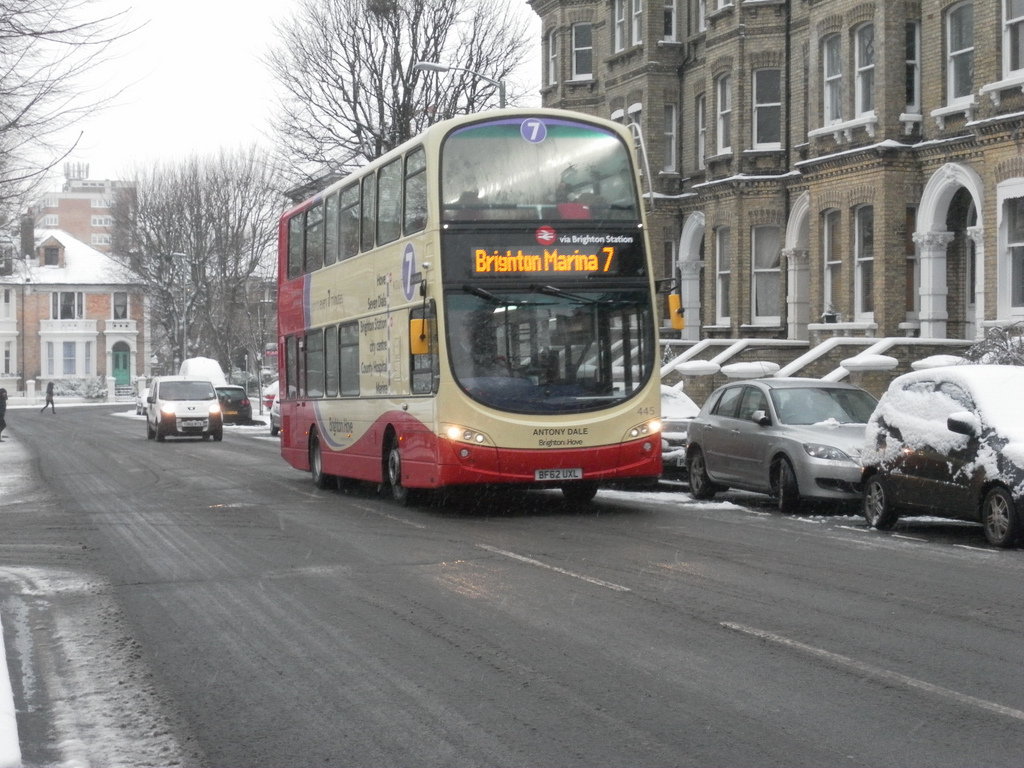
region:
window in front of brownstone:
[547, 35, 561, 84]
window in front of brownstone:
[573, 21, 596, 81]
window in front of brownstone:
[821, 207, 846, 318]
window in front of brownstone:
[852, 204, 873, 322]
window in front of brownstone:
[695, 95, 707, 169]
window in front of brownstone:
[713, 64, 736, 155]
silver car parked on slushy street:
[687, 371, 894, 512]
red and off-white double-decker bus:
[270, 101, 672, 509]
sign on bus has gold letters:
[445, 231, 643, 276]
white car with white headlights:
[144, 368, 227, 438]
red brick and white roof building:
[1, 216, 153, 407]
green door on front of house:
[110, 342, 134, 391]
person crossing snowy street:
[39, 379, 63, 418]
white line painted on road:
[470, 535, 638, 605]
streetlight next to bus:
[412, 57, 512, 118]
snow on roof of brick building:
[26, 226, 153, 392]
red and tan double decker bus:
[269, 102, 668, 507]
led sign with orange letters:
[450, 232, 650, 476]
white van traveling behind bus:
[138, 99, 666, 493]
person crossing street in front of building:
[20, 372, 100, 418]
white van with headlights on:
[140, 375, 227, 445]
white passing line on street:
[450, 523, 685, 631]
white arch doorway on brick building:
[906, 150, 989, 346]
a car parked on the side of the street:
[674, 371, 883, 518]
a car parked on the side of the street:
[212, 377, 252, 426]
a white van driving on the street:
[143, 370, 227, 443]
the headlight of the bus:
[444, 423, 460, 443]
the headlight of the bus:
[643, 415, 663, 432]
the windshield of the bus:
[443, 282, 652, 401]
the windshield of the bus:
[438, 115, 638, 218]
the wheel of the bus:
[301, 423, 334, 475]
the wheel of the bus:
[377, 426, 415, 499]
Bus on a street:
[263, 99, 681, 526]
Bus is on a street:
[263, 96, 696, 526]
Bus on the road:
[269, 102, 693, 526]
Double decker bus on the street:
[258, 102, 682, 539]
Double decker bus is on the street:
[263, 102, 693, 532]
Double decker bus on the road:
[266, 98, 668, 523]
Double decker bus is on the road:
[260, 98, 673, 531]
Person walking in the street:
[35, 368, 70, 420]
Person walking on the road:
[27, 370, 70, 419]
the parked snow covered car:
[681, 376, 879, 519]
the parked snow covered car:
[860, 363, 1022, 534]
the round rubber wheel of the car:
[680, 445, 712, 496]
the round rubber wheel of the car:
[773, 453, 796, 512]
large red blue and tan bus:
[277, 105, 660, 511]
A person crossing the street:
[1, 380, 1022, 766]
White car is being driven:
[146, 375, 222, 440]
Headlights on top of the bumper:
[437, 422, 660, 489]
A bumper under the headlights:
[438, 419, 664, 486]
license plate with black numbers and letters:
[533, 467, 582, 481]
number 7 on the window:
[441, 115, 639, 223]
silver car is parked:
[689, 377, 880, 514]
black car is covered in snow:
[861, 368, 1021, 545]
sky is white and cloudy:
[0, 1, 542, 276]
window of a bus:
[441, 128, 629, 218]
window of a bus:
[440, 299, 646, 411]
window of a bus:
[406, 317, 446, 393]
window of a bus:
[333, 331, 360, 386]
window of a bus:
[308, 334, 328, 393]